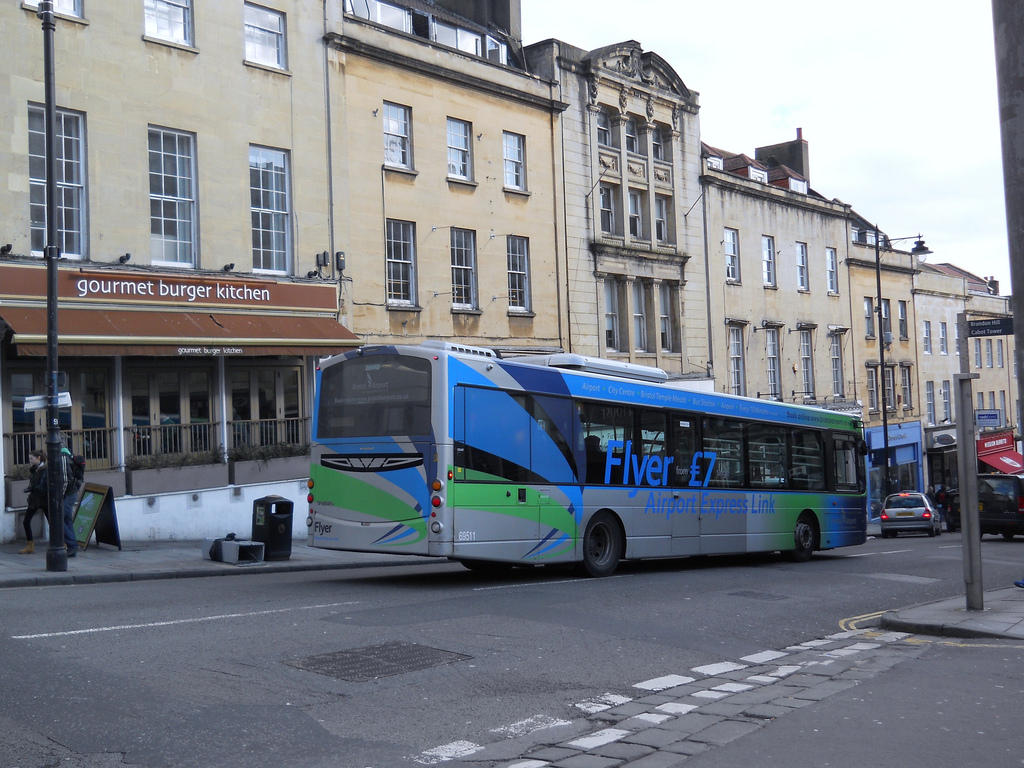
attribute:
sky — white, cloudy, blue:
[620, 5, 973, 211]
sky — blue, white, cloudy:
[762, 28, 1017, 229]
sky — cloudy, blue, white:
[734, 28, 1000, 253]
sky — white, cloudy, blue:
[688, 28, 1008, 201]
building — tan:
[321, 46, 576, 440]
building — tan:
[621, 119, 944, 502]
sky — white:
[832, 35, 915, 157]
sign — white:
[74, 197, 260, 357]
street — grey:
[322, 616, 610, 733]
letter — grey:
[74, 247, 107, 300]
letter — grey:
[135, 136, 242, 325]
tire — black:
[543, 508, 647, 569]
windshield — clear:
[672, 374, 1016, 515]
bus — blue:
[221, 212, 816, 750]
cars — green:
[338, 279, 866, 737]